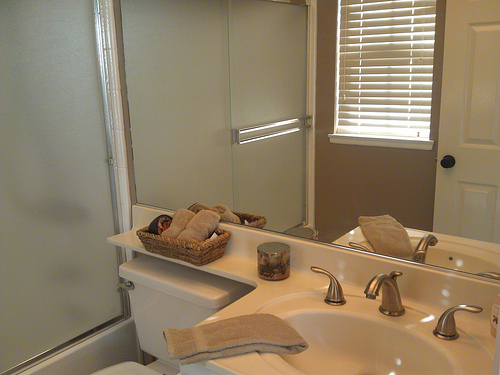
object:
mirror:
[117, 1, 499, 281]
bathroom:
[1, 0, 499, 374]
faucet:
[364, 270, 406, 316]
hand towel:
[161, 312, 310, 364]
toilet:
[90, 257, 249, 375]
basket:
[136, 218, 233, 266]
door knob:
[440, 154, 455, 169]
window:
[336, 0, 437, 141]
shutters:
[335, 0, 435, 141]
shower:
[0, 1, 122, 374]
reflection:
[315, 0, 447, 243]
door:
[431, 0, 499, 243]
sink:
[251, 309, 459, 374]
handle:
[309, 265, 347, 305]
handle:
[432, 302, 485, 341]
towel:
[159, 208, 197, 238]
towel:
[178, 210, 221, 241]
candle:
[257, 241, 290, 280]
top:
[256, 241, 288, 254]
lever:
[116, 280, 134, 290]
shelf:
[103, 207, 267, 284]